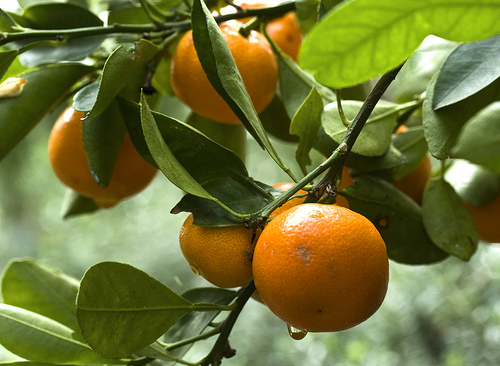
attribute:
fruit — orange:
[183, 27, 276, 120]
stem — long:
[240, 21, 257, 39]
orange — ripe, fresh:
[172, 11, 336, 140]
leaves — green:
[137, 68, 303, 216]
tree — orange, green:
[32, 33, 490, 361]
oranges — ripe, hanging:
[157, 164, 426, 333]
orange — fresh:
[250, 195, 396, 348]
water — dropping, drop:
[279, 309, 314, 347]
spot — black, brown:
[307, 299, 330, 325]